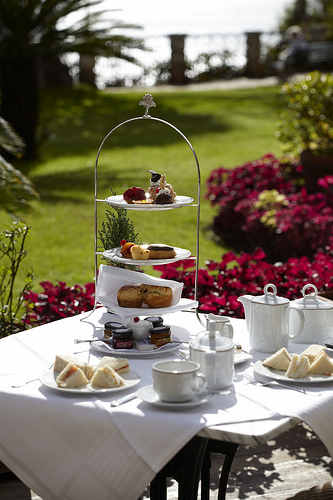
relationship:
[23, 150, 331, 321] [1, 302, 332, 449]
flowers behind table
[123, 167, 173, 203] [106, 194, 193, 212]
pastries on plate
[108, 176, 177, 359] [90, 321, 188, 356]
pastries are on shelf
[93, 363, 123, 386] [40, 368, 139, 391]
sandwich on plate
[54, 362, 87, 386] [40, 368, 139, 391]
sandwich on plate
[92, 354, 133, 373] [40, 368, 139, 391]
sandwich on plate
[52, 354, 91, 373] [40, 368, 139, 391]
sandwich on plate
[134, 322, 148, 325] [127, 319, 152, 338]
butter in container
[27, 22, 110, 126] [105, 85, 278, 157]
tree by grass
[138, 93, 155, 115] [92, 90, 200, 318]
decorative piece on top of tray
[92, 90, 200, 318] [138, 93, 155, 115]
tray has decorative piece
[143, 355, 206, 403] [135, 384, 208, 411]
cup on saucer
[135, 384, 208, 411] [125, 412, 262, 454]
saucer on table edge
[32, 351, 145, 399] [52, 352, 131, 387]
plate has sandwiches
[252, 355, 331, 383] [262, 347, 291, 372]
plate has sandwich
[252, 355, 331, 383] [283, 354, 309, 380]
plate has sandwich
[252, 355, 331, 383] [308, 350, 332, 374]
plate has sandwich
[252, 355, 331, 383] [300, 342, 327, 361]
plate has sandwich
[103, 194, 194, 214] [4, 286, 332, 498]
platter on table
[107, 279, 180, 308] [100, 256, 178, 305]
pastries on napkin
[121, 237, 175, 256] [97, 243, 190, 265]
pastries on platter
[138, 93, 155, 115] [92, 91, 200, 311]
decorative piece on top of stand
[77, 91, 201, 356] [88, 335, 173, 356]
rack has plate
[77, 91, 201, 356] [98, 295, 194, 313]
rack has plate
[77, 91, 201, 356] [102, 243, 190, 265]
rack has platter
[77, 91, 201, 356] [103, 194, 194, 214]
rack has platter